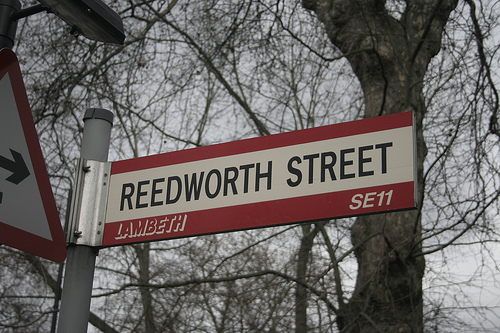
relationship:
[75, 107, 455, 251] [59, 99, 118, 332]
sign on pole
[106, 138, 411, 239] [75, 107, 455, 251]
writing on sign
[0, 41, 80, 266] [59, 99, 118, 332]
sign on pole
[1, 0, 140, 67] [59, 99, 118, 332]
light on pole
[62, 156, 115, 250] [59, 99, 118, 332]
brace on pole